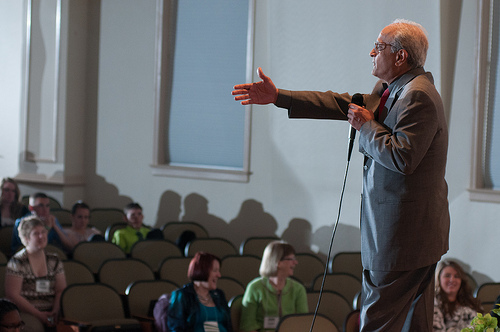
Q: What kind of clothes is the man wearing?
A: A suit.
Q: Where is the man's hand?
A: In front of him.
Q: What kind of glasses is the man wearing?
A: Eye glasses.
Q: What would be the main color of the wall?
A: White.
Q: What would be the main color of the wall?
A: White.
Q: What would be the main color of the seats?
A: Tan.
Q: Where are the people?
A: In the audience.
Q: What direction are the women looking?
A: To the right.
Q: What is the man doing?
A: Giving a speech.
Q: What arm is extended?
A: Right arm.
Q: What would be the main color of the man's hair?
A: Gray.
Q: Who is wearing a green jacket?
A: A woman.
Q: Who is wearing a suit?
A: The man.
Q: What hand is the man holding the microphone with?
A: His left.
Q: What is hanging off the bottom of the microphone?
A: A cord.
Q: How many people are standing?
A: One.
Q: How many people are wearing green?
A: Two.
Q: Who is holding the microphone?
A: The man.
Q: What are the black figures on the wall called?
A: Shadows.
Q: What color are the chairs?
A: Brown.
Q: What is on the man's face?
A: Glasses.